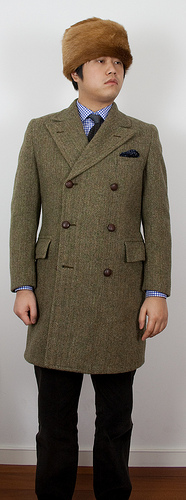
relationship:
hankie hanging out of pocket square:
[119, 148, 141, 160] [119, 157, 141, 194]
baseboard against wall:
[146, 449, 185, 467] [150, 392, 175, 440]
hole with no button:
[64, 262, 77, 272] [104, 265, 114, 281]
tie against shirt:
[90, 112, 100, 130] [80, 108, 90, 123]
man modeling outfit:
[17, 17, 169, 496] [9, 20, 180, 494]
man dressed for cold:
[17, 17, 169, 496] [21, 117, 156, 370]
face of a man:
[86, 56, 122, 103] [17, 17, 169, 496]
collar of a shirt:
[73, 102, 87, 116] [82, 103, 93, 120]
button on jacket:
[104, 265, 114, 281] [33, 114, 160, 372]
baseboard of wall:
[146, 449, 185, 467] [150, 392, 175, 440]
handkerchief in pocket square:
[120, 145, 140, 157] [119, 157, 141, 194]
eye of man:
[98, 58, 107, 68] [17, 17, 169, 496]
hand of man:
[140, 295, 166, 334] [17, 17, 169, 496]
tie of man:
[90, 112, 100, 130] [17, 17, 169, 496]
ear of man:
[73, 71, 77, 81] [17, 17, 169, 496]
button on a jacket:
[104, 265, 114, 281] [33, 114, 160, 372]